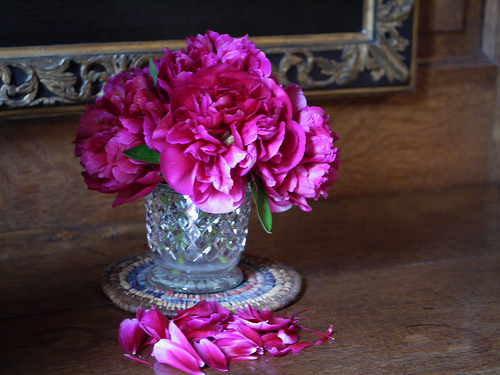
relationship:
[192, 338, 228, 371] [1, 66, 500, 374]
petal on top of table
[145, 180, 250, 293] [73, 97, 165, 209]
vase holding flower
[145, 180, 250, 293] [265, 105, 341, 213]
vase holds flower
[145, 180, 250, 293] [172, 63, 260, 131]
vase holds flower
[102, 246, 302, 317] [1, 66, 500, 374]
coaster on top of table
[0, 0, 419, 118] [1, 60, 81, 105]
frame has pattern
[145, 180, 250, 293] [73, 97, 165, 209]
vase holds flower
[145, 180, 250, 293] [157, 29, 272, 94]
vase holds flower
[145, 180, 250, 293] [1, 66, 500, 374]
vase on top of table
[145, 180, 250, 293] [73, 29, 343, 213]
vase holds flowers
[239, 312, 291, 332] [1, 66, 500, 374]
petal on table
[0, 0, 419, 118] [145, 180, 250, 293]
frame behind vase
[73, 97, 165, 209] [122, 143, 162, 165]
flower has leaf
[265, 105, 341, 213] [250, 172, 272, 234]
flower has leaf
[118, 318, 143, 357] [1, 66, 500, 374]
petal on top of table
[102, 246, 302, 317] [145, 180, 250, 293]
coaster underneath vase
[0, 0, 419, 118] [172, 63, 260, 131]
frame behind flower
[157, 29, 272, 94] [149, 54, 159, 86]
flower has leaf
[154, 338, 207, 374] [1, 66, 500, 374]
petal laying on table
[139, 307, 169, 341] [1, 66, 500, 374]
petal laying on table